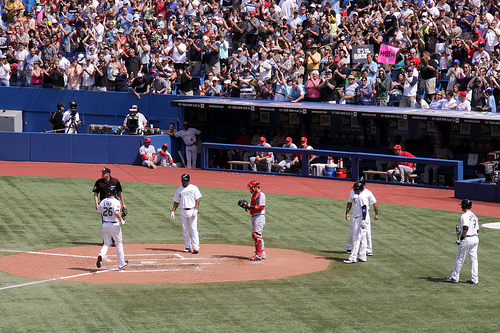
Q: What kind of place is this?
A: It is a field.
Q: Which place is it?
A: It is a field.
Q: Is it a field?
A: Yes, it is a field.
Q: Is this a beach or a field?
A: It is a field.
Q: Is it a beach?
A: No, it is a field.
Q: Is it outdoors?
A: Yes, it is outdoors.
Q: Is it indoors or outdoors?
A: It is outdoors.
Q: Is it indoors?
A: No, it is outdoors.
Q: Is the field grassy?
A: Yes, the field is grassy.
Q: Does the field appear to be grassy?
A: Yes, the field is grassy.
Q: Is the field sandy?
A: No, the field is grassy.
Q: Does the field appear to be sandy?
A: No, the field is grassy.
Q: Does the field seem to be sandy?
A: No, the field is grassy.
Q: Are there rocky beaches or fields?
A: No, there is a field but it is grassy.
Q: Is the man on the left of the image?
A: Yes, the man is on the left of the image.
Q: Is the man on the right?
A: No, the man is on the left of the image.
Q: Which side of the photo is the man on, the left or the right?
A: The man is on the left of the image.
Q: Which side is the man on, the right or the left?
A: The man is on the left of the image.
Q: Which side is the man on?
A: The man is on the left of the image.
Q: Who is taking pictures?
A: The man is taking pictures.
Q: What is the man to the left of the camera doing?
A: The man is taking pictures.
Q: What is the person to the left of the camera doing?
A: The man is taking pictures.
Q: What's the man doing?
A: The man is taking pictures.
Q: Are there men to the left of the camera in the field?
A: Yes, there is a man to the left of the camera.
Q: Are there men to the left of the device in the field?
A: Yes, there is a man to the left of the camera.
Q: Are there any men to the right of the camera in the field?
A: No, the man is to the left of the camera.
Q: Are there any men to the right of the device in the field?
A: No, the man is to the left of the camera.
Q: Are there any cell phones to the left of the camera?
A: No, there is a man to the left of the camera.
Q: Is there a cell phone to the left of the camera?
A: No, there is a man to the left of the camera.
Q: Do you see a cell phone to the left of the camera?
A: No, there is a man to the left of the camera.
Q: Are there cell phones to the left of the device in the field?
A: No, there is a man to the left of the camera.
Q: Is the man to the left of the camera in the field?
A: Yes, the man is to the left of the camera.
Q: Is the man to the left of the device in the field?
A: Yes, the man is to the left of the camera.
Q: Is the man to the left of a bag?
A: No, the man is to the left of the camera.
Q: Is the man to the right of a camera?
A: No, the man is to the left of a camera.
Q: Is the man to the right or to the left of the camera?
A: The man is to the left of the camera.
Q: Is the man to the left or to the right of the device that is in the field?
A: The man is to the left of the camera.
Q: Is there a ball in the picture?
A: No, there are no balls.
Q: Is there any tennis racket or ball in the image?
A: No, there are no balls or rackets.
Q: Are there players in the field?
A: Yes, there is a player in the field.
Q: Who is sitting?
A: The player is sitting.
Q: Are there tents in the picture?
A: No, there are no tents.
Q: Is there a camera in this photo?
A: Yes, there is a camera.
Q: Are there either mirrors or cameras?
A: Yes, there is a camera.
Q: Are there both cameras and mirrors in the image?
A: No, there is a camera but no mirrors.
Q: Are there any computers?
A: No, there are no computers.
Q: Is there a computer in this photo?
A: No, there are no computers.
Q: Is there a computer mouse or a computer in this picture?
A: No, there are no computers or computer mice.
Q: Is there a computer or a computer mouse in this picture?
A: No, there are no computers or computer mice.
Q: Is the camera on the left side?
A: Yes, the camera is on the left of the image.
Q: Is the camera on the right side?
A: No, the camera is on the left of the image.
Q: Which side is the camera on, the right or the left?
A: The camera is on the left of the image.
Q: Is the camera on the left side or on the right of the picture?
A: The camera is on the left of the image.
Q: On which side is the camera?
A: The camera is on the left of the image.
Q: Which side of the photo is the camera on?
A: The camera is on the left of the image.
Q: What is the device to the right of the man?
A: The device is a camera.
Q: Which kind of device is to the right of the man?
A: The device is a camera.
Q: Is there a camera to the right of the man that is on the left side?
A: Yes, there is a camera to the right of the man.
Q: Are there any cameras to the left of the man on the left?
A: No, the camera is to the right of the man.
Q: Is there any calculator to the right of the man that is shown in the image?
A: No, there is a camera to the right of the man.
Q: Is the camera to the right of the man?
A: Yes, the camera is to the right of the man.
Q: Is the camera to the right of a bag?
A: No, the camera is to the right of the man.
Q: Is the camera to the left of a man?
A: No, the camera is to the right of a man.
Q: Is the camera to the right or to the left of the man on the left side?
A: The camera is to the right of the man.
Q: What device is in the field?
A: The device is a camera.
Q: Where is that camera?
A: The camera is in the field.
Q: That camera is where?
A: The camera is in the field.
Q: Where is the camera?
A: The camera is in the field.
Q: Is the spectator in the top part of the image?
A: Yes, the spectator is in the top of the image.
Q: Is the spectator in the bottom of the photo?
A: No, the spectator is in the top of the image.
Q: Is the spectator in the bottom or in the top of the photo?
A: The spectator is in the top of the image.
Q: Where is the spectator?
A: The spectator is in the field.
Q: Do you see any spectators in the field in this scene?
A: Yes, there is a spectator in the field.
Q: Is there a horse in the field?
A: No, there is a spectator in the field.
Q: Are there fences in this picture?
A: Yes, there is a fence.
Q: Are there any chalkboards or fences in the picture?
A: Yes, there is a fence.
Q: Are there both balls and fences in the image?
A: No, there is a fence but no balls.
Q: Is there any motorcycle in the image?
A: No, there are no motorcycles.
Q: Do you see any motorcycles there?
A: No, there are no motorcycles.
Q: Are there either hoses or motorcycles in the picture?
A: No, there are no motorcycles or hoses.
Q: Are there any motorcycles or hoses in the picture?
A: No, there are no motorcycles or hoses.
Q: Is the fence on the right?
A: No, the fence is on the left of the image.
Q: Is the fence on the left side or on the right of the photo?
A: The fence is on the left of the image.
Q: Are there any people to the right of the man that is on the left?
A: Yes, there is a person to the right of the man.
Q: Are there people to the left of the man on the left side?
A: No, the person is to the right of the man.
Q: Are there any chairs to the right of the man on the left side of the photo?
A: No, there is a person to the right of the man.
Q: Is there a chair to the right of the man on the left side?
A: No, there is a person to the right of the man.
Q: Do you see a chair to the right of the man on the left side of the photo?
A: No, there is a person to the right of the man.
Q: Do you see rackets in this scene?
A: No, there are no rackets.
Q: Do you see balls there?
A: No, there are no balls.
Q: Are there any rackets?
A: No, there are no rackets.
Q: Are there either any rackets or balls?
A: No, there are no rackets or balls.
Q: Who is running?
A: The player is running.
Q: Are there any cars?
A: No, there are no cars.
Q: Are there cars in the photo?
A: No, there are no cars.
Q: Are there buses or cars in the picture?
A: No, there are no cars or buses.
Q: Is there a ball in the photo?
A: No, there are no balls.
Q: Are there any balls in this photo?
A: No, there are no balls.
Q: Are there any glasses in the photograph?
A: No, there are no glasses.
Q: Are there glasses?
A: No, there are no glasses.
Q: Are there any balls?
A: No, there are no balls.